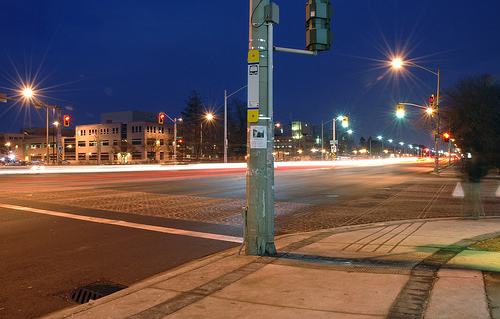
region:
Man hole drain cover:
[70, 279, 141, 309]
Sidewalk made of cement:
[41, 212, 492, 313]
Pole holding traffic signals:
[208, 1, 372, 269]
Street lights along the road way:
[302, 17, 439, 149]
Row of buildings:
[5, 117, 186, 168]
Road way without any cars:
[7, 162, 498, 317]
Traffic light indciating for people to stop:
[48, 102, 75, 132]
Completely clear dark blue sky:
[1, 11, 495, 153]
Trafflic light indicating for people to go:
[385, 99, 406, 129]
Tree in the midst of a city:
[437, 75, 497, 170]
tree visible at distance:
[446, 80, 498, 165]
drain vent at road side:
[76, 285, 104, 303]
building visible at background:
[77, 119, 110, 159]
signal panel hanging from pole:
[61, 112, 70, 125]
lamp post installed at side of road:
[433, 67, 441, 176]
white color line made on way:
[8, 203, 67, 222]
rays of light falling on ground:
[293, 156, 383, 166]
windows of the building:
[131, 124, 141, 131]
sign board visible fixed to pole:
[330, 144, 335, 151]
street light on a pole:
[378, 40, 449, 161]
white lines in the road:
[10, 189, 251, 274]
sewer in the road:
[60, 269, 138, 314]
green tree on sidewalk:
[438, 66, 497, 193]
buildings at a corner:
[72, 109, 180, 173]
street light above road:
[55, 108, 72, 132]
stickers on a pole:
[246, 112, 271, 155]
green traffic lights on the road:
[331, 101, 359, 146]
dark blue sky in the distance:
[77, 12, 212, 89]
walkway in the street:
[29, 175, 229, 232]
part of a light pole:
[380, 43, 410, 78]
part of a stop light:
[420, 85, 437, 131]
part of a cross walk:
[60, 164, 235, 253]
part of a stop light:
[52, 108, 81, 132]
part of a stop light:
[387, 96, 445, 118]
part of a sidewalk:
[300, 203, 434, 305]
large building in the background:
[69, 104, 196, 166]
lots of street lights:
[275, 102, 461, 174]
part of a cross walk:
[0, 160, 372, 255]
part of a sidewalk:
[360, 202, 469, 315]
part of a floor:
[342, 266, 368, 283]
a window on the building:
[97, 122, 107, 139]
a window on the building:
[122, 125, 129, 132]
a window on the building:
[155, 126, 172, 143]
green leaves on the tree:
[455, 116, 487, 174]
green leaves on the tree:
[460, 72, 494, 116]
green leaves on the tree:
[160, 93, 204, 115]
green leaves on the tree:
[217, 112, 241, 150]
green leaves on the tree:
[464, 102, 479, 163]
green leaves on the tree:
[442, 80, 486, 144]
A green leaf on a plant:
[469, 100, 471, 102]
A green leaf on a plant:
[483, 99, 484, 100]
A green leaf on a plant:
[473, 116, 478, 122]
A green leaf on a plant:
[474, 110, 476, 111]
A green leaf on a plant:
[456, 113, 460, 116]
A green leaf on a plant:
[471, 117, 473, 119]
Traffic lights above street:
[19, 60, 463, 143]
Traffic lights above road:
[5, 78, 462, 153]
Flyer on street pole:
[248, 123, 272, 155]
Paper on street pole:
[244, 123, 274, 155]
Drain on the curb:
[56, 268, 131, 300]